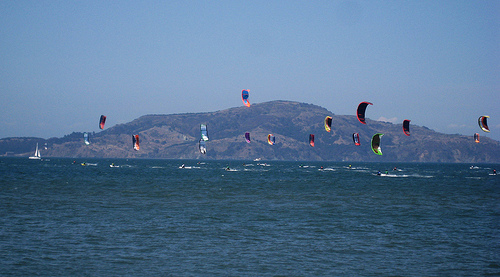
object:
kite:
[241, 88, 250, 107]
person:
[73, 161, 76, 164]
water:
[4, 164, 497, 271]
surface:
[2, 157, 498, 268]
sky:
[0, 10, 500, 137]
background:
[0, 1, 499, 165]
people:
[71, 160, 495, 176]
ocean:
[4, 165, 500, 277]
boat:
[29, 142, 42, 160]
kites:
[478, 115, 491, 133]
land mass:
[6, 100, 499, 163]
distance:
[9, 1, 498, 161]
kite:
[370, 133, 384, 155]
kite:
[132, 134, 140, 151]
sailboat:
[34, 142, 41, 156]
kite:
[267, 134, 276, 146]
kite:
[83, 131, 91, 146]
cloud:
[375, 114, 475, 136]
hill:
[10, 101, 500, 160]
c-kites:
[356, 101, 373, 125]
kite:
[308, 134, 315, 147]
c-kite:
[199, 124, 210, 155]